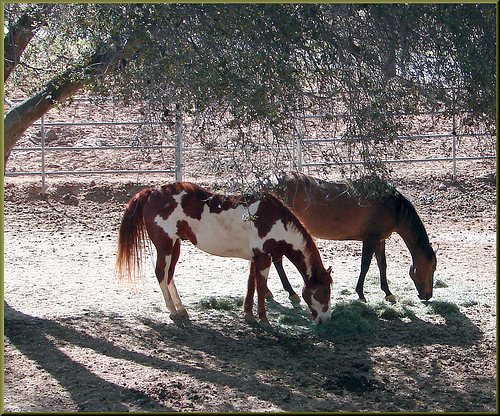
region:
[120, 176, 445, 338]
Two horses grazing on grass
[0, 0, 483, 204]
Large tree providing horses shade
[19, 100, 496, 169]
Metal fence to keep horses in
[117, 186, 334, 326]
Brown and white horse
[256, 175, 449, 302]
brown horse with dark mane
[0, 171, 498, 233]
uneven dirt that slopes up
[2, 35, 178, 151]
strong tree branch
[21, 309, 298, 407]
shadow of a tree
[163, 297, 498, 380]
shadow of two horses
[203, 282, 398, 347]
grass on which horses are grazing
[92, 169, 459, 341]
two horses grazing in the grass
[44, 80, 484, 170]
silver metal fence behind horses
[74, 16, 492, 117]
green leaves of the tree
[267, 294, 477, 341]
green grass where horses are grazing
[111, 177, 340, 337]
brown and white horse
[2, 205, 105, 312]
sandy ground near the horses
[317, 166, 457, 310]
dark brown horse grazing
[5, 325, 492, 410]
shadows of horses and tree on ground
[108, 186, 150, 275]
tail of brown and white horse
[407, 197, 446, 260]
mane of the dark brown horse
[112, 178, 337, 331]
Brown and white horse.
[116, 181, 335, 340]
Spotted horse feeding on grass.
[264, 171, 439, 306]
Brown horse feeding on grass.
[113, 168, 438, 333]
Two horses feeding on grass.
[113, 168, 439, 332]
Two horses in an enclosure.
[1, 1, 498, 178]
Tree providing shade for horses.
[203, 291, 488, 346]
Clumps of green grass.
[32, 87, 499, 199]
Metal fence enclosure.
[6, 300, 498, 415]
Tree shadow caste on ground.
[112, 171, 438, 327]
Horses at peace feeding on grass.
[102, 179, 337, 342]
a white and brown horse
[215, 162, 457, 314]
a brown horse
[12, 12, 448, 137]
a large tree branch above two horses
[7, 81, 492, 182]
a metal fence near two horses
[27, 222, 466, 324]
a patch of grass under two horses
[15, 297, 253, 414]
the shadow of a large tree trunk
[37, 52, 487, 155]
a patch of dirt on the far side of a fence from two horses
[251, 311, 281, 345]
a multicolored horses's right front hoof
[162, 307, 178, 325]
a multicolored horses's right rear hoof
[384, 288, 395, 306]
a brown horses left front hoof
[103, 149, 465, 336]
Two horses in a prairie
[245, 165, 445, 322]
Brown horse eating grass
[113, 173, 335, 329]
White horse with brown spots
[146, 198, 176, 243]
Thigh of spotted horse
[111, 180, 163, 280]
Brown hairy tail of spotted horse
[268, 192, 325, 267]
Brown mane of horse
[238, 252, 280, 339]
Front legs of horse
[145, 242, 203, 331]
Back legs of horse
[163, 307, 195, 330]
Hoof of spotted horse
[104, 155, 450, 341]
Two horses eating hay